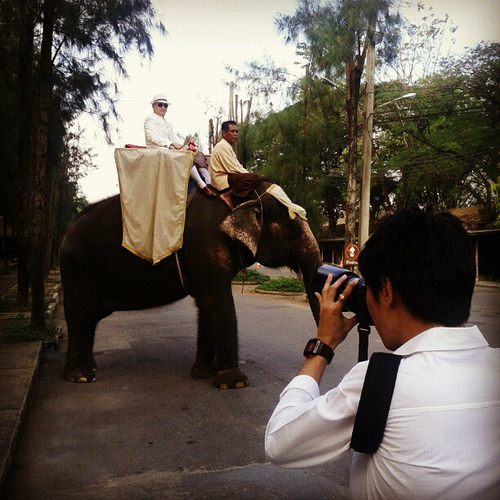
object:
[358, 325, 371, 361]
strap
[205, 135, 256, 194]
man shirt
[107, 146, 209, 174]
bench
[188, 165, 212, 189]
pants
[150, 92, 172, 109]
hat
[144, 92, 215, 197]
guy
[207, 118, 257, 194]
guy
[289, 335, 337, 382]
wrist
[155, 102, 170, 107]
sunglasses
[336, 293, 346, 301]
ring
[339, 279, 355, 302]
finger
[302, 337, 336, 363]
watch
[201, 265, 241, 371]
front legs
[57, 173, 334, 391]
elephant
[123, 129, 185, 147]
coffee table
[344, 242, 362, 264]
sign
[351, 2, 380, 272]
pole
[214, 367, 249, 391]
foot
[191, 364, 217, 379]
foot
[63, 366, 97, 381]
foot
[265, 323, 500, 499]
shirt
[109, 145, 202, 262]
cloth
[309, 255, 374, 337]
camera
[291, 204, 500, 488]
guy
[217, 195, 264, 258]
ear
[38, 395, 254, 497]
road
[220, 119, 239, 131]
hair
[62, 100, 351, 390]
picture